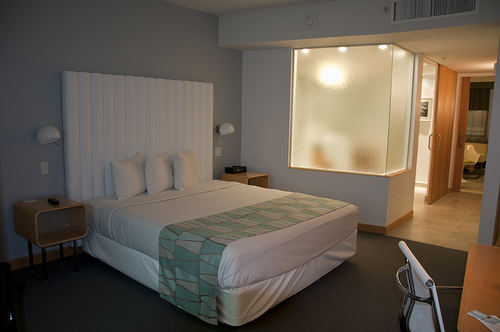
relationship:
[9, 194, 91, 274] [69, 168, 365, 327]
night table on right of bed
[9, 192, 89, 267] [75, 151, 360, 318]
night table on left of bed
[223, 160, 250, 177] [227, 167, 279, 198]
stuff over table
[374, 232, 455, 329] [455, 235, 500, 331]
chair in front of desk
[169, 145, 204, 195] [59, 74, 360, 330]
pillow on bed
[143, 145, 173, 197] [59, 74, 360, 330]
pillow on bed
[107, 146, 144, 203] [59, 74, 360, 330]
pillow on bed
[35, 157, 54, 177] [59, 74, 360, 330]
lightswitch next to bed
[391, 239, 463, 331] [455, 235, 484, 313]
chair at desk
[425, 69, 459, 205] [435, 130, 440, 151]
door with handle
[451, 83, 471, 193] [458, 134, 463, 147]
door with handle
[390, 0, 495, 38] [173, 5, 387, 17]
vent next to ceiling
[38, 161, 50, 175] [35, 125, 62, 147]
lightswitch for bulb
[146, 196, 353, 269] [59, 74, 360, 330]
blanket on bed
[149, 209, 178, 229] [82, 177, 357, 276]
part of mattress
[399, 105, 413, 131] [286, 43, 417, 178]
part of window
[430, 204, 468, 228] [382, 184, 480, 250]
part of floor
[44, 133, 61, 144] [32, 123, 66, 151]
part of bulb